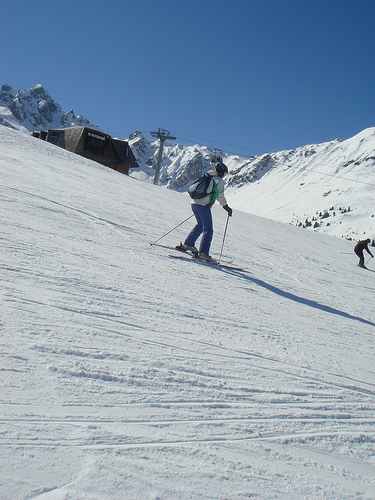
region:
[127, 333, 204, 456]
Snow on the slopes.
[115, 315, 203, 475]
Ski tracks in the snow.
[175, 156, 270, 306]
Skier going down the slope.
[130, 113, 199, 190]
Ski lift.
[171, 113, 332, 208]
Snow cap mountains.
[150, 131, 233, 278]
Skier with backpack on.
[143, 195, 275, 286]
Skier with two ski poles.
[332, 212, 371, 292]
Skier bent over going down the hill.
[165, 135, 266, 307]
Skier with purple pants.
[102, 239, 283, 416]
Lots of snow on the slopes.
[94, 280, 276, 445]
ski tracks on white snow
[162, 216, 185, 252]
silver long ski poles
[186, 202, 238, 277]
blue pants on skier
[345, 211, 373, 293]
black shadowed skier on track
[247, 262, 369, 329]
shadow of skier on ground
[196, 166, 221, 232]
white black and blue backpack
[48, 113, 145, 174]
brown wooded building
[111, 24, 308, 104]
clear blue sky above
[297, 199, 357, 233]
grouped pine trees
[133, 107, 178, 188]
electric poles for energy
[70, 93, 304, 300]
skier moving down a slope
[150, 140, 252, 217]
black backpack with blue and white teardrop shapes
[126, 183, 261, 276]
one pole in front and one in back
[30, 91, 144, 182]
angled structure at top of slope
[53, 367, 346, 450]
ski marks across the snow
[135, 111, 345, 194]
pole and cable of ski lift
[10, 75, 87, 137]
jagged outcrop of rocks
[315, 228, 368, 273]
skier leaning forward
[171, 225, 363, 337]
thin shadow of skier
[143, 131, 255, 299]
skier wearing cap and gloves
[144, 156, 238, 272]
skier wearing blue pants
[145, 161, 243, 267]
skier wearing pack on back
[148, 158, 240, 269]
skier wearing blue helmet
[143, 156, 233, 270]
skier carrying black poles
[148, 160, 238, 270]
skier wearing white jacket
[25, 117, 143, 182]
brown ski lodge at top of mountain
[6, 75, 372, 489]
white snow covering ground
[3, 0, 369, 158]
bright blue clear sky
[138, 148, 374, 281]
two skiers visible on slope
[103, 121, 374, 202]
electrical wires visible in distance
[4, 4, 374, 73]
a cloudless blue sky.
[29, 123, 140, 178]
a brown ski lodge, behind a snow slope.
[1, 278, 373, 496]
white snow on the ground, with ski tracks.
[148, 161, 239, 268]
a man skiing down a snowy slope.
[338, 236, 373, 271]
a man in black, skiing on the snow in the distance.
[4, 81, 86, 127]
snow covered mountain top, in the background.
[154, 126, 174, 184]
large power-line pole in the distance.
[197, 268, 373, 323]
shadow of the skier in a white jacket.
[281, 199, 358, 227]
trees in the distance.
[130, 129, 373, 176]
a ridge of snowy mountain tops, behind a man's head.